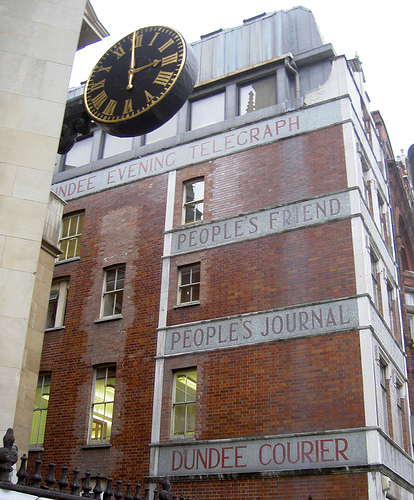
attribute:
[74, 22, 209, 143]
clock. — analog, round, black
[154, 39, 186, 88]
roman numerals. — gold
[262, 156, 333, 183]
brick. — red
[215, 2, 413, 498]
tall building. — brick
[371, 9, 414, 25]
sky. — overcast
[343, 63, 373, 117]
gray side. — grey